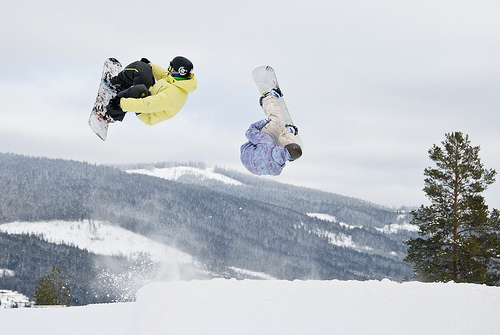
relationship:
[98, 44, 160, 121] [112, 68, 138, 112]
pants on legs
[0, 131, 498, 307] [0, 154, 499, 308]
trees on hill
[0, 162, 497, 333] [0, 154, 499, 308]
snow on hill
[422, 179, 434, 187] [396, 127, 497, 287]
needles on tree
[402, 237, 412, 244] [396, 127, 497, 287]
needles on tree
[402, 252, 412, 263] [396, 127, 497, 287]
needles on tree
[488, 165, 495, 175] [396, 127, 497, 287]
needles on tree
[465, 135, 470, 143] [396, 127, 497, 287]
needles on tree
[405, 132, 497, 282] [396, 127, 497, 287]
leaves on tree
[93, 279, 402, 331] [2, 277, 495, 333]
snowy surface on foreground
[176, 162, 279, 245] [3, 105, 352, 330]
snow on a hill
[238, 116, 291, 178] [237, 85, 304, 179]
jacket on a person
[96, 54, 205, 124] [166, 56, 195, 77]
person wearing helmet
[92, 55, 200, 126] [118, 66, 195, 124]
person wearing yellow coat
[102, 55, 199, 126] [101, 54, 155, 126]
person wearing black pants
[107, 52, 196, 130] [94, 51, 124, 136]
person doing trick on snowboard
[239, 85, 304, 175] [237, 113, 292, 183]
person wearing a coat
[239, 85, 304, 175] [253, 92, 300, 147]
person wearing pants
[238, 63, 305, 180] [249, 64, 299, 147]
person doing trick on snowboard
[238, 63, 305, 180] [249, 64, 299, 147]
person riding a snowboard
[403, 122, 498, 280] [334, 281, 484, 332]
tree on a mountain side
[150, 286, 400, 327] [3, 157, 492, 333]
snow covering ground